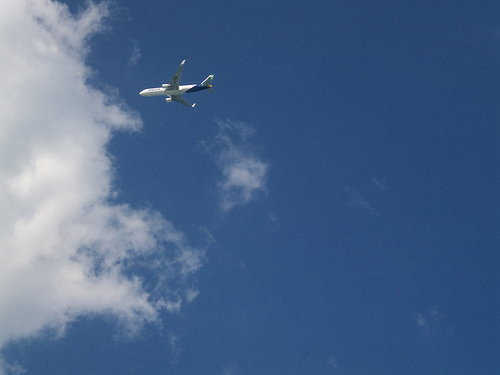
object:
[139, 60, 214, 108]
plane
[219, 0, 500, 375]
sky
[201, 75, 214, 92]
tail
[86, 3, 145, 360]
edge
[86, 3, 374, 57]
part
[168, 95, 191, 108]
wing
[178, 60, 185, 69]
left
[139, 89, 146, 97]
tip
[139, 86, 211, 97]
bottom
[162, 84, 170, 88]
engine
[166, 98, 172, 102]
engine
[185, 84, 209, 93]
blue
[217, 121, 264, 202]
little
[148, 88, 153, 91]
windows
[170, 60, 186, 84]
wing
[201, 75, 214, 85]
part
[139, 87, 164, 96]
white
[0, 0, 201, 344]
cloud